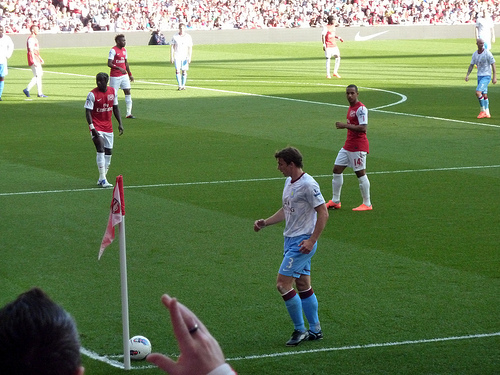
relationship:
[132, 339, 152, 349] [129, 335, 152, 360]
logos on ball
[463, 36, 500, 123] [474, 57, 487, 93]
man wearing uniform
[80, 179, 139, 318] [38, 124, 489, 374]
flag on field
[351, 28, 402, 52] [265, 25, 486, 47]
logo on wall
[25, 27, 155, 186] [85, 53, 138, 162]
men wearing uniforms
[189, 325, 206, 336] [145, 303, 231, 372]
ring on hand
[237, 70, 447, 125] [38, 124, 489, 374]
lines on field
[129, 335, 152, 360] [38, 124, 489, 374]
ball on field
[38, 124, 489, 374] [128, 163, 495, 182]
field has stripes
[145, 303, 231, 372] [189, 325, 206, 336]
hand has ring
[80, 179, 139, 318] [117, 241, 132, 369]
flag on pole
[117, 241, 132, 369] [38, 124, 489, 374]
pole in field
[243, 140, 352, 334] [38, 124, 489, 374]
player on field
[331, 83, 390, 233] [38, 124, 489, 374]
player on field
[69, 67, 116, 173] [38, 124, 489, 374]
player on field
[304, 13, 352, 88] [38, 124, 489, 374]
player on field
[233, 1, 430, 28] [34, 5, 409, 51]
fans in stands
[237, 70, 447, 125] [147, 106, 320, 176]
lines on grass